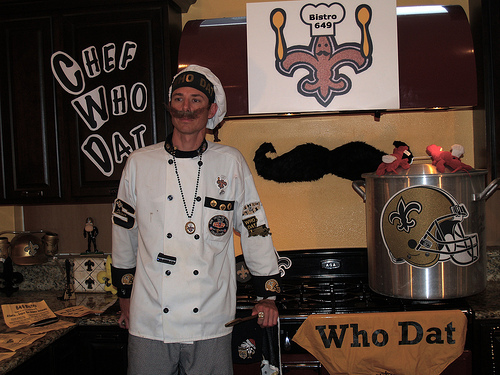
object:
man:
[112, 65, 279, 374]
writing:
[50, 40, 149, 178]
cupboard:
[0, 2, 167, 207]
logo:
[378, 184, 480, 270]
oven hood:
[177, 5, 481, 119]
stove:
[229, 247, 475, 375]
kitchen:
[1, 0, 500, 319]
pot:
[351, 143, 498, 300]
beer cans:
[0, 230, 70, 265]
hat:
[168, 63, 229, 129]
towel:
[289, 309, 467, 375]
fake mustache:
[162, 101, 215, 118]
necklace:
[170, 140, 204, 237]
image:
[269, 1, 374, 108]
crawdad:
[421, 143, 474, 179]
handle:
[28, 316, 64, 325]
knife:
[0, 316, 65, 332]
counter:
[0, 291, 119, 375]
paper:
[0, 300, 78, 335]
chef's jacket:
[111, 139, 281, 344]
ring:
[255, 310, 264, 321]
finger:
[256, 310, 265, 327]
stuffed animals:
[376, 141, 415, 176]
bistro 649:
[309, 11, 339, 29]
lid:
[375, 155, 476, 178]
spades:
[83, 259, 97, 275]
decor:
[65, 255, 114, 292]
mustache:
[254, 141, 424, 181]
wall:
[180, 0, 474, 264]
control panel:
[320, 257, 345, 272]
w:
[69, 85, 113, 131]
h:
[112, 84, 129, 116]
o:
[129, 81, 149, 113]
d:
[74, 134, 115, 176]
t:
[129, 123, 148, 151]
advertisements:
[51, 1, 412, 183]